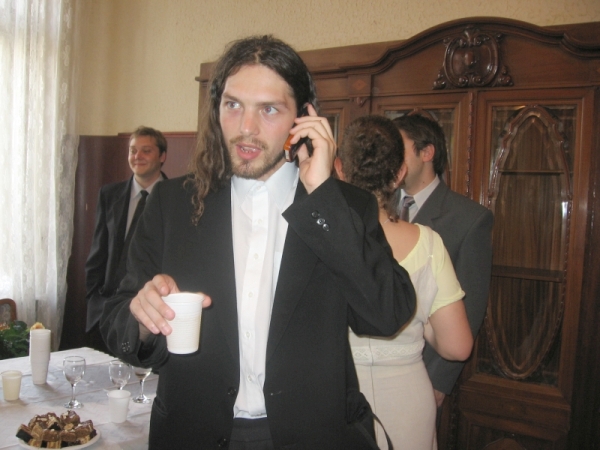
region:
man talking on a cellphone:
[166, 30, 336, 346]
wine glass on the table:
[57, 348, 94, 408]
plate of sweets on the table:
[17, 407, 105, 449]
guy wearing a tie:
[116, 124, 176, 212]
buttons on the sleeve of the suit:
[304, 204, 333, 239]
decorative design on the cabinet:
[429, 27, 508, 96]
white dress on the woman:
[418, 236, 451, 310]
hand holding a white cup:
[138, 267, 218, 363]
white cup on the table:
[112, 388, 128, 423]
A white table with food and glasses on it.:
[0, 346, 159, 448]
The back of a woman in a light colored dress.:
[332, 110, 470, 446]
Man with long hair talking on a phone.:
[81, 31, 413, 445]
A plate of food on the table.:
[12, 408, 96, 446]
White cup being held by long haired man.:
[156, 290, 201, 350]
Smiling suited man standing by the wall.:
[81, 123, 165, 345]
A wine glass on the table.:
[60, 354, 84, 408]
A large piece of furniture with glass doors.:
[198, 12, 595, 445]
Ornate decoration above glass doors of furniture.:
[430, 24, 510, 90]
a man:
[96, 27, 420, 447]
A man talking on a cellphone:
[114, 32, 424, 448]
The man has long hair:
[99, 32, 418, 449]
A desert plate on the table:
[17, 404, 109, 448]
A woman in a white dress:
[318, 112, 468, 448]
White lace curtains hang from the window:
[5, 3, 80, 351]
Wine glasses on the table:
[58, 353, 154, 411]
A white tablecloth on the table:
[0, 340, 169, 448]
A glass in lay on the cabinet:
[479, 94, 584, 403]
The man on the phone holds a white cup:
[103, 31, 414, 449]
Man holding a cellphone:
[182, 19, 328, 192]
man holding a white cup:
[147, 259, 211, 362]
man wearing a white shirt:
[213, 170, 293, 424]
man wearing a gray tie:
[389, 196, 417, 214]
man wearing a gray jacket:
[383, 184, 497, 406]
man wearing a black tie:
[120, 180, 148, 258]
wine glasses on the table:
[59, 351, 87, 409]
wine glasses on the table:
[99, 356, 134, 397]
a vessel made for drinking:
[157, 291, 203, 356]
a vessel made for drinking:
[133, 358, 151, 405]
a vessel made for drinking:
[103, 379, 130, 421]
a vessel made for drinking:
[110, 360, 129, 393]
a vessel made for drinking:
[60, 354, 88, 408]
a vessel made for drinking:
[2, 369, 20, 402]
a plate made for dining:
[16, 432, 94, 447]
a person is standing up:
[79, 126, 175, 325]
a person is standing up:
[104, 39, 422, 447]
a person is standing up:
[335, 114, 482, 448]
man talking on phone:
[148, 36, 342, 440]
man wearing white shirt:
[139, 30, 355, 434]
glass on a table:
[90, 354, 133, 390]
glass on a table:
[57, 349, 93, 407]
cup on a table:
[0, 362, 27, 402]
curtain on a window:
[20, 7, 83, 261]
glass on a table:
[93, 378, 135, 426]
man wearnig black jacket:
[134, 36, 356, 444]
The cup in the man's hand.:
[164, 289, 203, 352]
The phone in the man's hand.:
[285, 109, 316, 155]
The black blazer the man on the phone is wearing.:
[106, 180, 411, 447]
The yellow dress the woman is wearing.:
[345, 213, 459, 449]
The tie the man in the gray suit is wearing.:
[396, 193, 415, 222]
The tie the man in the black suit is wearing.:
[128, 191, 146, 237]